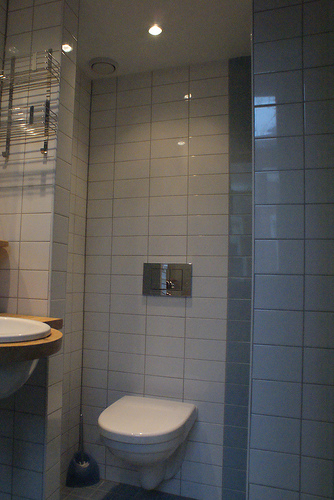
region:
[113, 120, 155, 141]
white bathroom tile on wall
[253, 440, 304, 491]
white bathroom tile on wall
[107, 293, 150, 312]
white bathroom tile on wall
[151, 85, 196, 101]
white bathroom tile on wall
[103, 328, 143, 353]
white bathroom tile on wall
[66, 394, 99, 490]
toilet plunger in corner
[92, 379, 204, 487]
white ceramic toilet bowl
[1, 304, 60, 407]
white ceramic sink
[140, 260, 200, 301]
silver shiny panel with flush button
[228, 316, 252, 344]
blue tile on wall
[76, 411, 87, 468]
Toilet clean brush in holder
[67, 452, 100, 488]
Blue holder for a toilet cleaning brush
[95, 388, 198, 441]
White toilet lid over toilet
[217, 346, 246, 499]
Blue tile stripe on wall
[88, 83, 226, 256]
White tile on a bathroom wall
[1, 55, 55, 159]
Metal hanging shelf on a bathroom wall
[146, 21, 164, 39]
Light inset in a bathroom ceiling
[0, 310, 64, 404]
Bathroom sink next to toilet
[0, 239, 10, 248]
Wooden counter top in a bathroom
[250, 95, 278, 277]
Reflection on bathroom tile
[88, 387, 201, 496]
a white toilet bowl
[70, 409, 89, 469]
a toilet brush with a blue handle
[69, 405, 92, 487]
a toilet brush and holder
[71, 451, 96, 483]
a blue toilet brush holder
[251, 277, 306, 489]
a tile wall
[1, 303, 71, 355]
a white bathroom sink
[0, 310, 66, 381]
a tan bathroom counter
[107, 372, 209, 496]
a toilet bowl attached to a wall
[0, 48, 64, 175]
a metal towel rack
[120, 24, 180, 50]
a light mounted to the cieling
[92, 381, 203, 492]
a toilet attached to the wall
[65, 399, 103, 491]
a toilet brush in it's holder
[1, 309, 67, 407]
a sink attached to the wall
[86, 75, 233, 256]
the wall is made of tile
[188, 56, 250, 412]
teal and white tiles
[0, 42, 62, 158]
a steel shelf on the wall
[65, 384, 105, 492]
a toilet cleaner in the corner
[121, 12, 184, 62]
a light attached to the ceiling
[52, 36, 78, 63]
light reflected on the tile wall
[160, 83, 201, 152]
two lights reflected on the wall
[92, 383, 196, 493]
A porcelain toilet on a wall.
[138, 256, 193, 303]
A metal collection window.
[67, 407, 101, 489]
A grey toilet bowl cleaner.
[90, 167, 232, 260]
White tiles in a bathroom.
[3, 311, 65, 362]
A brown bathroom counter.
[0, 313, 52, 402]
A deep sink basin.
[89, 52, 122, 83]
A smoke detector on a ceiling.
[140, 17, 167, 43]
Lights recessed in the ceiling.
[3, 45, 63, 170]
A metal rack on the wall.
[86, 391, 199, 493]
The toilet is white.